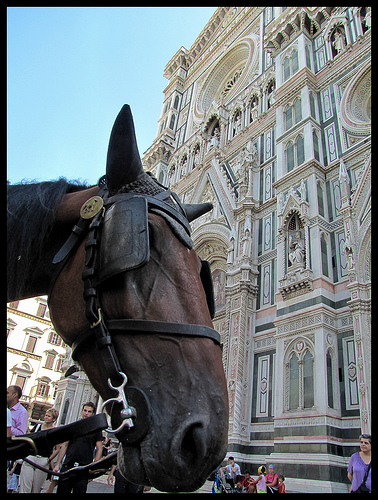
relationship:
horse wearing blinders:
[4, 97, 247, 493] [86, 192, 153, 294]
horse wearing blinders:
[4, 97, 247, 493] [196, 255, 223, 322]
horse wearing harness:
[4, 97, 247, 493] [8, 164, 238, 468]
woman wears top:
[339, 431, 377, 495] [344, 451, 373, 493]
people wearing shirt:
[6, 381, 35, 496] [4, 398, 31, 447]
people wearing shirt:
[52, 395, 108, 494] [60, 419, 108, 468]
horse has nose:
[4, 97, 247, 493] [172, 417, 234, 475]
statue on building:
[285, 226, 309, 270] [45, 8, 370, 495]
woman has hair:
[339, 431, 377, 495] [358, 433, 371, 447]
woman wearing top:
[339, 431, 377, 495] [344, 451, 373, 493]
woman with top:
[339, 431, 377, 495] [344, 451, 373, 493]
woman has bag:
[339, 431, 377, 495] [351, 459, 372, 496]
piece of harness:
[77, 195, 107, 223] [8, 164, 238, 468]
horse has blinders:
[4, 97, 247, 493] [86, 192, 153, 294]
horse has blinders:
[4, 97, 247, 493] [196, 255, 223, 322]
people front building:
[273, 474, 287, 494] [45, 8, 370, 495]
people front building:
[266, 462, 280, 495] [45, 8, 370, 495]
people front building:
[247, 462, 268, 497] [45, 8, 370, 495]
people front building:
[237, 468, 253, 495] [45, 8, 370, 495]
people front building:
[216, 452, 245, 496] [45, 8, 370, 495]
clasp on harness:
[95, 369, 141, 436] [8, 164, 238, 468]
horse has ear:
[4, 97, 247, 493] [179, 192, 216, 227]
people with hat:
[247, 462, 268, 497] [255, 464, 266, 476]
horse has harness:
[4, 97, 247, 493] [8, 164, 238, 468]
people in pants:
[20, 404, 62, 495] [15, 450, 53, 499]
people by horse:
[52, 395, 108, 494] [4, 97, 247, 493]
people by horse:
[20, 404, 62, 495] [4, 97, 247, 493]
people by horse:
[6, 381, 35, 496] [4, 97, 247, 493]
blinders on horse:
[86, 192, 153, 294] [4, 97, 247, 493]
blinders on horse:
[196, 255, 223, 322] [4, 97, 247, 493]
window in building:
[183, 36, 263, 116] [45, 8, 370, 495]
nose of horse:
[172, 417, 234, 475] [4, 97, 247, 493]